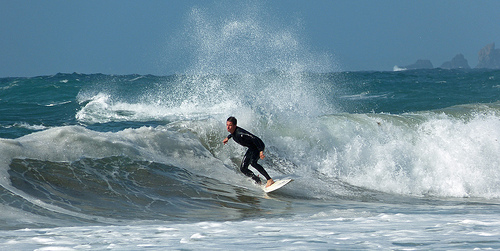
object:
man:
[221, 116, 274, 188]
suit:
[226, 126, 272, 183]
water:
[23, 75, 442, 217]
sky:
[17, 2, 439, 83]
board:
[251, 178, 292, 193]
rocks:
[393, 40, 500, 70]